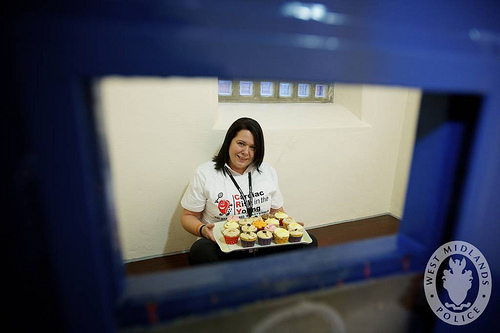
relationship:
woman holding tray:
[209, 110, 279, 212] [215, 228, 223, 248]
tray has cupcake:
[215, 228, 223, 248] [226, 226, 241, 235]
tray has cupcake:
[215, 228, 223, 248] [278, 233, 288, 239]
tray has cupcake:
[215, 228, 223, 248] [246, 222, 254, 228]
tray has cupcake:
[215, 228, 223, 248] [280, 213, 284, 217]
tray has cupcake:
[215, 228, 223, 248] [260, 232, 270, 239]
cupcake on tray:
[260, 232, 270, 239] [215, 228, 223, 248]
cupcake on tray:
[292, 228, 302, 236] [215, 228, 223, 248]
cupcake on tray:
[226, 226, 241, 235] [215, 228, 223, 248]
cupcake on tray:
[246, 222, 254, 228] [215, 228, 223, 248]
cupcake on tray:
[278, 233, 288, 239] [215, 228, 223, 248]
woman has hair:
[209, 110, 279, 212] [258, 137, 267, 156]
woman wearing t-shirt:
[209, 110, 279, 212] [197, 178, 216, 193]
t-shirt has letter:
[197, 178, 216, 193] [234, 194, 243, 201]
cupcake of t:
[280, 213, 284, 217] [217, 233, 223, 245]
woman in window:
[209, 110, 279, 212] [408, 91, 433, 212]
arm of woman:
[182, 217, 197, 229] [209, 110, 279, 212]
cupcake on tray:
[280, 213, 284, 217] [215, 228, 223, 248]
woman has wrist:
[209, 110, 279, 212] [202, 228, 208, 236]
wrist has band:
[202, 228, 208, 236] [199, 222, 221, 239]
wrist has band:
[202, 228, 208, 236] [197, 222, 200, 231]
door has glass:
[328, 270, 412, 331] [120, 204, 151, 225]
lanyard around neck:
[236, 184, 243, 200] [234, 166, 242, 173]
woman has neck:
[209, 110, 279, 212] [234, 166, 242, 173]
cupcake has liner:
[260, 232, 270, 239] [260, 238, 269, 243]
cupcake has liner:
[292, 228, 302, 236] [294, 237, 300, 240]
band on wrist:
[199, 222, 221, 239] [202, 228, 208, 236]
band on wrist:
[197, 222, 200, 231] [202, 228, 208, 236]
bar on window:
[232, 82, 241, 93] [262, 84, 272, 90]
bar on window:
[308, 84, 320, 97] [408, 91, 433, 212]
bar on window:
[292, 82, 298, 97] [408, 91, 433, 212]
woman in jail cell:
[209, 110, 279, 212] [319, 141, 398, 243]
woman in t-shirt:
[209, 110, 279, 212] [197, 178, 216, 193]